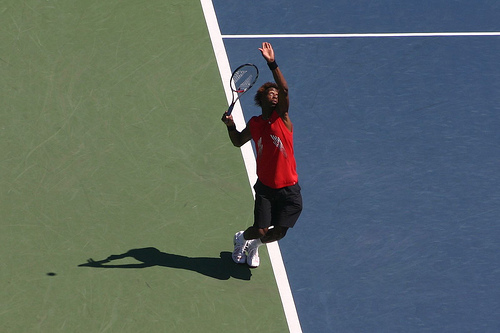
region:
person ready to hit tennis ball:
[206, 29, 322, 279]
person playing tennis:
[205, 46, 320, 269]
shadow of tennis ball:
[45, 260, 65, 290]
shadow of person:
[92, 238, 247, 286]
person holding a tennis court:
[225, 46, 258, 136]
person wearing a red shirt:
[240, 93, 296, 179]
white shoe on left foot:
[250, 240, 265, 272]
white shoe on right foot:
[227, 226, 242, 257]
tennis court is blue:
[336, 94, 418, 183]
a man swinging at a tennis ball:
[220, 40, 306, 267]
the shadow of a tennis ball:
[44, 268, 59, 283]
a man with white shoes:
[226, 230, 265, 272]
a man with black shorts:
[248, 175, 307, 230]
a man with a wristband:
[263, 58, 280, 71]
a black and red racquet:
[218, 60, 260, 122]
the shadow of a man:
[75, 244, 255, 283]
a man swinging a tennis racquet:
[218, 35, 303, 271]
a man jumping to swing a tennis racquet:
[218, 40, 315, 267]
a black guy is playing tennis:
[219, 64, 304, 284]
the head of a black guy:
[253, 82, 277, 114]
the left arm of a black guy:
[264, 58, 299, 115]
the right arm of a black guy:
[219, 112, 255, 152]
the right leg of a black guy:
[245, 189, 270, 246]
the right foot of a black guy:
[222, 230, 249, 262]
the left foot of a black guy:
[249, 237, 265, 272]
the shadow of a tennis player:
[85, 227, 159, 284]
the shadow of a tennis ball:
[29, 255, 73, 284]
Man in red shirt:
[201, 42, 352, 314]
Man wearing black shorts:
[216, 42, 332, 294]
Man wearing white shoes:
[190, 35, 345, 300]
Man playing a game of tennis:
[219, 39, 314, 284]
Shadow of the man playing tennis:
[46, 240, 296, 302]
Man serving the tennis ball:
[214, 39, 306, 284]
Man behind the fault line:
[226, 160, 307, 331]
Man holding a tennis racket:
[216, 40, 311, 152]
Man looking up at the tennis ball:
[214, 29, 308, 159]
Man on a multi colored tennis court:
[209, 23, 490, 326]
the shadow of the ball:
[44, 270, 59, 279]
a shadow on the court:
[73, 243, 258, 293]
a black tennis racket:
[219, 60, 261, 123]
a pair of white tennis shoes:
[229, 227, 269, 271]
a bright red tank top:
[242, 106, 302, 193]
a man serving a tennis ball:
[208, 35, 308, 279]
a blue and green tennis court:
[30, 5, 476, 317]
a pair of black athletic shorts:
[251, 181, 304, 233]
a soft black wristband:
[264, 59, 280, 72]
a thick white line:
[197, 0, 259, 191]